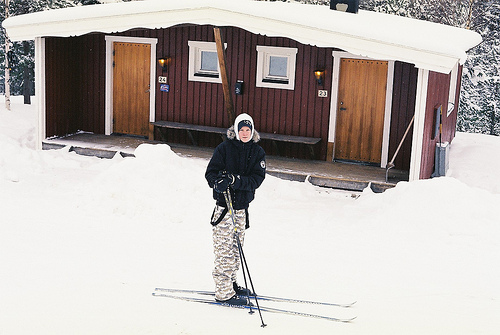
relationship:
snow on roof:
[202, 0, 480, 51] [1, 4, 488, 74]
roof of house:
[1, 4, 488, 74] [5, 2, 467, 181]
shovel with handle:
[362, 115, 420, 176] [386, 111, 430, 150]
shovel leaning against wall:
[362, 115, 420, 176] [377, 67, 421, 122]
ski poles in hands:
[223, 190, 270, 328] [214, 172, 239, 189]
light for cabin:
[309, 70, 323, 81] [4, 2, 482, 194]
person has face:
[209, 112, 258, 309] [236, 124, 253, 144]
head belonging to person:
[233, 109, 255, 143] [142, 110, 289, 275]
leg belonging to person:
[212, 207, 239, 299] [209, 112, 258, 309]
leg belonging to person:
[233, 205, 246, 288] [168, 114, 323, 322]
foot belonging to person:
[227, 295, 250, 306] [209, 112, 258, 309]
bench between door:
[156, 118, 320, 158] [336, 55, 387, 167]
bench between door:
[156, 118, 320, 158] [109, 40, 149, 135]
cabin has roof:
[4, 2, 482, 194] [1, 4, 488, 74]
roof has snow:
[1, 4, 488, 74] [403, 27, 463, 42]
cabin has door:
[4, 2, 482, 194] [323, 46, 397, 165]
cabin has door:
[4, 2, 482, 194] [103, 29, 158, 137]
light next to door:
[309, 70, 323, 81] [336, 55, 387, 167]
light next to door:
[156, 51, 169, 70] [111, 42, 151, 137]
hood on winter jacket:
[225, 109, 264, 146] [182, 117, 276, 214]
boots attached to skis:
[224, 282, 248, 308] [153, 283, 358, 327]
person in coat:
[209, 112, 258, 309] [143, 129, 350, 236]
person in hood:
[209, 112, 258, 309] [231, 110, 257, 145]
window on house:
[257, 47, 301, 91] [5, 2, 467, 181]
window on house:
[187, 38, 229, 85] [5, 2, 467, 181]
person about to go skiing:
[209, 112, 258, 309] [150, 175, 356, 326]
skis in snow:
[152, 281, 357, 322] [0, 156, 499, 329]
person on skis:
[209, 112, 258, 309] [146, 285, 356, 330]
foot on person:
[227, 295, 250, 306] [201, 110, 270, 316]